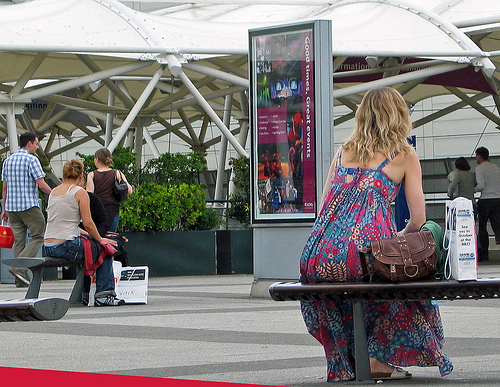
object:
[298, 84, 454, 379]
woman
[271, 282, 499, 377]
bench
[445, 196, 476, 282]
bag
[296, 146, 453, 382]
dress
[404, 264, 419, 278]
buckle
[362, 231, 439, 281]
purse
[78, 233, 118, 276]
strap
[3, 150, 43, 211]
shirt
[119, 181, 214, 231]
shrub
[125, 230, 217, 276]
planter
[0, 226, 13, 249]
bag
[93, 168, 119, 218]
tank top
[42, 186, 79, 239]
tank top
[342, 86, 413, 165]
hair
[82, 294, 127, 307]
shoes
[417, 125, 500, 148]
wall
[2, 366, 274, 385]
line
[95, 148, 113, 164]
hair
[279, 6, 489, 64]
pipe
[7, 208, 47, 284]
pants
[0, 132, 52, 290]
man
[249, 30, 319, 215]
sign